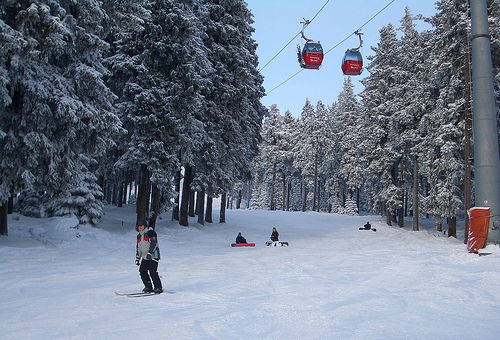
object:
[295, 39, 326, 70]
cars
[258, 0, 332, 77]
rail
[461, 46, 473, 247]
pole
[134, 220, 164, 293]
man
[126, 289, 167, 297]
skis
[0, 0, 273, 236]
trees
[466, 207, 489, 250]
mat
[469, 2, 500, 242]
pole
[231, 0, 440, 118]
sky